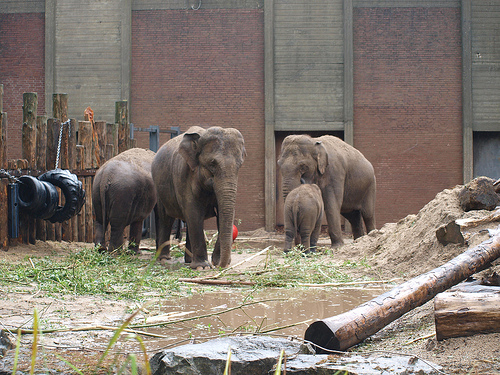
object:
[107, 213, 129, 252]
leg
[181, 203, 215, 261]
leg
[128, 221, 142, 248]
leg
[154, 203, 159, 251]
leg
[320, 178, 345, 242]
leg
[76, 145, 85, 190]
post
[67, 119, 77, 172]
post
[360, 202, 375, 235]
leg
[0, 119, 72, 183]
rope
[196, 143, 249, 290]
trunk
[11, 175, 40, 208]
black tire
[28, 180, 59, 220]
black tire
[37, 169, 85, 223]
black tire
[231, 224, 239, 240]
red object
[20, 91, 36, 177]
logs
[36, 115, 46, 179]
logs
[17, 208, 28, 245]
logs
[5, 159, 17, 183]
logs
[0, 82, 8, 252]
logs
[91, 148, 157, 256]
elephant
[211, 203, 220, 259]
leg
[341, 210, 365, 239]
leg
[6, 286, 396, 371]
puddle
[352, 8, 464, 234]
wall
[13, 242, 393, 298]
trees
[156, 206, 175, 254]
leg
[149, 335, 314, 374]
rocks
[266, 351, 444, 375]
rocks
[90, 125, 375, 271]
four elpehants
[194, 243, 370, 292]
grass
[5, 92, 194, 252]
elephant enclosure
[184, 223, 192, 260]
leg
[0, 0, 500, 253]
building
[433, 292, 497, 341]
log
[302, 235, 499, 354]
log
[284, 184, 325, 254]
baby elephant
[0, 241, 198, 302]
grass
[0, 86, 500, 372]
enclsure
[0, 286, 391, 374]
pool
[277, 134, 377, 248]
behind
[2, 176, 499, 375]
ground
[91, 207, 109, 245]
leg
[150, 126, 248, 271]
elephant